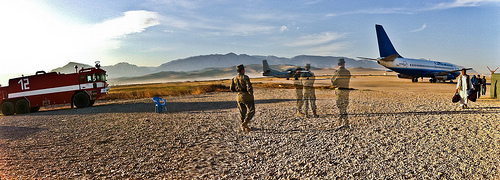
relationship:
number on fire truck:
[11, 79, 31, 97] [0, 60, 110, 115]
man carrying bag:
[453, 66, 475, 105] [467, 89, 480, 101]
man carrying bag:
[453, 66, 475, 105] [452, 91, 462, 106]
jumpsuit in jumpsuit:
[229, 64, 256, 132] [227, 73, 254, 130]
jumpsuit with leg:
[229, 64, 256, 132] [244, 96, 261, 127]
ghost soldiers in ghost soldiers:
[329, 58, 351, 130] [329, 58, 351, 130]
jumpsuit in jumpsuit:
[301, 63, 319, 117] [300, 77, 320, 117]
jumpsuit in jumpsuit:
[293, 68, 303, 116] [293, 79, 307, 113]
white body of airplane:
[358, 47, 480, 83] [366, 19, 476, 84]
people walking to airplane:
[448, 64, 486, 114] [352, 17, 484, 94]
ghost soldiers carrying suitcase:
[329, 58, 351, 130] [452, 92, 461, 103]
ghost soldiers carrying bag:
[329, 58, 351, 130] [467, 88, 477, 102]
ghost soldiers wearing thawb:
[329, 58, 351, 130] [449, 74, 473, 103]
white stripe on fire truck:
[8, 79, 103, 107] [2, 60, 109, 118]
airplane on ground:
[359, 23, 469, 81] [3, 72, 498, 176]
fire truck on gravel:
[0, 60, 110, 115] [8, 102, 137, 154]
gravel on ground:
[0, 90, 500, 180] [290, 126, 339, 173]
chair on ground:
[152, 96, 169, 113] [3, 72, 498, 176]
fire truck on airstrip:
[0, 60, 110, 115] [2, 69, 497, 176]